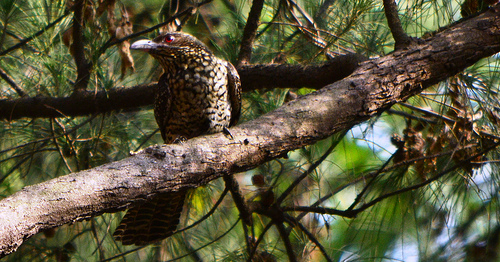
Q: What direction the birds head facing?
A: Left.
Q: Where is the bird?
A: On the branch.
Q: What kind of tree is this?
A: Pine.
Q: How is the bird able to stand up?
A: Claws.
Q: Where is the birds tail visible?
A: Below the branch.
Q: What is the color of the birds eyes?
A: Red.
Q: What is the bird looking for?
A: A mate.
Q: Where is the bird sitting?
A: On a log.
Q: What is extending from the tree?
A: A branch.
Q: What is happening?
A: A bird sitting on a branch.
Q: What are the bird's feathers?
A: Grey and brown.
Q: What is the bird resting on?
A: A tree branch.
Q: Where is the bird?
A: On a tree branch.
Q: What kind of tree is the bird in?
A: A pine tree.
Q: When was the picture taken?
A: Daytime.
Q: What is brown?
A: Bird.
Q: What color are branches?
A: Brown.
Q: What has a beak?
A: The bird.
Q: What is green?
A: Leaves.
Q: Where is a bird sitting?
A: On a tree branch.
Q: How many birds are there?
A: One.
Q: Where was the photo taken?
A: In the forest.